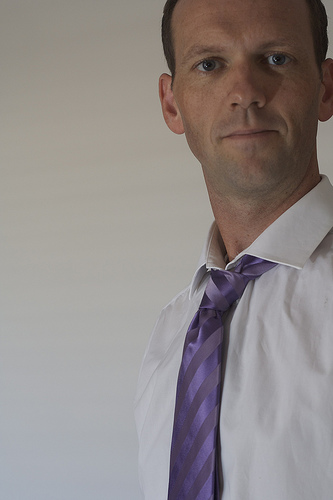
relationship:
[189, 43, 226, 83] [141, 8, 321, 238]
eye of man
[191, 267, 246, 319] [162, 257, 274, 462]
knot of tie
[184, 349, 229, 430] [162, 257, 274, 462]
pattern on tie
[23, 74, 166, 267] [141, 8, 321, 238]
wall behind man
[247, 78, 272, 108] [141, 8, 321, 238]
nose of man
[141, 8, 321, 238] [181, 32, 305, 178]
man has face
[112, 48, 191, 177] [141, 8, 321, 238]
ear of man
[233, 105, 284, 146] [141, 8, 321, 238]
mouth of man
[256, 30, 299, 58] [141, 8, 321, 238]
eyebrow of man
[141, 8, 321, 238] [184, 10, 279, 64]
man has forehead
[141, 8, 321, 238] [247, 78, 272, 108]
man has nose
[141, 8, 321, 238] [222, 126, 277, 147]
man has lip